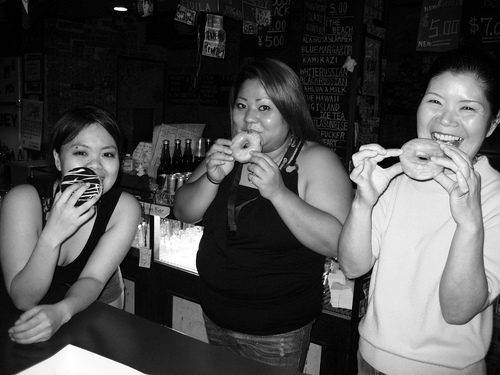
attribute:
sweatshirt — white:
[349, 143, 499, 363]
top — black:
[4, 187, 136, 345]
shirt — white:
[373, 187, 487, 322]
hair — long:
[254, 60, 329, 143]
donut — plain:
[231, 129, 266, 162]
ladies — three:
[0, 54, 498, 374]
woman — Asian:
[5, 103, 143, 346]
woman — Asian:
[171, 52, 351, 372]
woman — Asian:
[337, 43, 497, 373]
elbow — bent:
[304, 227, 390, 315]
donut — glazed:
[397, 135, 447, 183]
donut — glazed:
[228, 130, 264, 161]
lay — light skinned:
[444, 79, 463, 99]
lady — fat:
[175, 60, 352, 373]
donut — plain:
[391, 136, 456, 183]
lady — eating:
[198, 90, 366, 347]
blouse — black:
[194, 110, 312, 372]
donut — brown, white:
[64, 165, 101, 204]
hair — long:
[230, 57, 317, 144]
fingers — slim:
[426, 155, 455, 170]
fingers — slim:
[438, 145, 468, 166]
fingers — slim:
[375, 144, 405, 160]